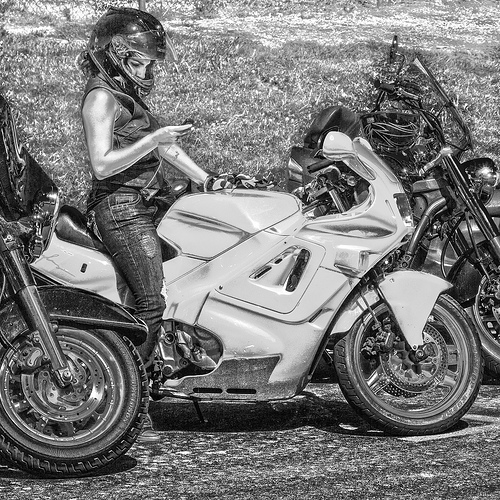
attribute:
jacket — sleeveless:
[80, 71, 170, 201]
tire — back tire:
[0, 321, 148, 476]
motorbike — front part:
[2, 88, 489, 478]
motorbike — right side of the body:
[27, 107, 484, 432]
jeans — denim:
[110, 191, 170, 367]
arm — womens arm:
[82, 89, 201, 178]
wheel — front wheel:
[0, 287, 197, 497]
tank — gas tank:
[143, 167, 308, 259]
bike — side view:
[23, 125, 485, 427]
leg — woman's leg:
[94, 177, 174, 385]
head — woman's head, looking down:
[83, 3, 168, 101]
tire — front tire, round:
[344, 276, 484, 428]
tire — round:
[321, 266, 483, 424]